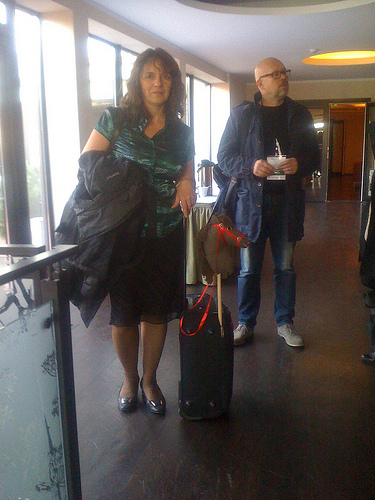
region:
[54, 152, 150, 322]
the jacket is black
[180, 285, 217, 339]
the ribbon is red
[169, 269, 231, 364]
the ribbon is red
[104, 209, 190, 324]
a black chiffon type pencil skirt.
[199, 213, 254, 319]
a pony head on a stick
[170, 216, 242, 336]
a red bridle and reins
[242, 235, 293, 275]
worn spots on jeans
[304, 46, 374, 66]
large round holes in the ceiling for lights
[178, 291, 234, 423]
a black roll behind suitcase.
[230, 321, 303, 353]
off white walking shoes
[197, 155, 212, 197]
a self serve area for coffee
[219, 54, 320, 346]
a man with no hair and glasses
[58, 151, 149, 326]
a lady carries a black coat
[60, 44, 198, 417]
a woman in a green shirt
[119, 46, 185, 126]
the woman has brown hair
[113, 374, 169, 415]
blue shoes with gold buckles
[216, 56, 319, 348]
a bald man with glasses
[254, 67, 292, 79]
glasses with dark frames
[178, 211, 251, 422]
a stick pony sticking out of the suitcase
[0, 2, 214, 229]
several large windows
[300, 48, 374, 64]
a large circle that has a light in it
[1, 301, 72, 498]
a panel of frosted glass with designs on it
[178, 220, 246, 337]
red ribbon is on the stick pony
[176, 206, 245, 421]
stick pony in a suitcase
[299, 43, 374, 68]
round recessed ceiling light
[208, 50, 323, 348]
man that is wearing glasses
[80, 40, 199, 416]
woman wearing a skirt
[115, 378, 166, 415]
navy blue professional shoes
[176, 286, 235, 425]
black suitcase with wheels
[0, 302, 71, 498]
frosted glass panel with etching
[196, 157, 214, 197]
steel air hotpot for coffee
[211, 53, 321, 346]
man wearing denim jeans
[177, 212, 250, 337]
brown stick pony with red strap